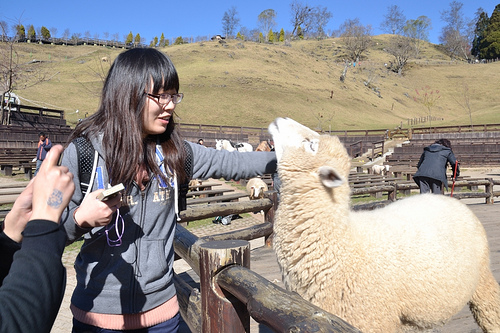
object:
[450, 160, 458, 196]
handle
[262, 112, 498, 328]
sheep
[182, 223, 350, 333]
gate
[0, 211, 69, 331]
black jacket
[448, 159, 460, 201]
shovel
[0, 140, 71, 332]
person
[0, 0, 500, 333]
picture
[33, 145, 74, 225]
on hand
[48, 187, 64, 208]
stamp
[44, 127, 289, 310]
grey coat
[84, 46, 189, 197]
black hair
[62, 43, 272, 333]
girl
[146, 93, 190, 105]
glasses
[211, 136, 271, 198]
group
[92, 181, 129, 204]
phone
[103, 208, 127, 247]
earbuds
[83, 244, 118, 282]
pocket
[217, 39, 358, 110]
hill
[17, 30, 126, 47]
bridge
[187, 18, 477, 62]
background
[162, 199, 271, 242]
fence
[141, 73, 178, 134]
face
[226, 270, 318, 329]
wood rail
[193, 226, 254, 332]
post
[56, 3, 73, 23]
blue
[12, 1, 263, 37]
above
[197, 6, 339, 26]
sky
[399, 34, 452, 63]
hillside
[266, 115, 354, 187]
head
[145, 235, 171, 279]
pocket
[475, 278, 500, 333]
leg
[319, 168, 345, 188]
ear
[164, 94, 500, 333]
sheep pen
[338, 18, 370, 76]
tree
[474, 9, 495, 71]
pine tree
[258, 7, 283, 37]
tree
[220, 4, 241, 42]
tree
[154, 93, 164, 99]
eyes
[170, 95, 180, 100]
woman's eyes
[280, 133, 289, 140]
white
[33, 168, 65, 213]
back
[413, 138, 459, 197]
person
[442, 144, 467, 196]
sweeping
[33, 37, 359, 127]
large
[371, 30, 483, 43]
distance